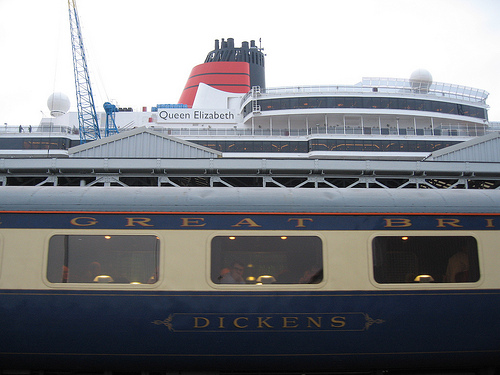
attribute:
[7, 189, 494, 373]
train — blue, cream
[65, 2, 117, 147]
crane — blue, vertical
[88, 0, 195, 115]
sky — white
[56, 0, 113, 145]
crane — blue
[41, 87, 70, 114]
dome — round, white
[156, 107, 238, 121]
queen elizabeth — on boat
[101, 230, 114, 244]
light — on boat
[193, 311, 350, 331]
word dickens — on boat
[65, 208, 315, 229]
letters — yellow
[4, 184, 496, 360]
train car — blue, white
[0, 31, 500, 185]
boat — red, blue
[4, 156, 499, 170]
stripe — white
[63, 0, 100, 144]
crane — blue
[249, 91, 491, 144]
balcony — empty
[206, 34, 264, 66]
stacks — red, black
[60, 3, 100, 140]
ladder — blue